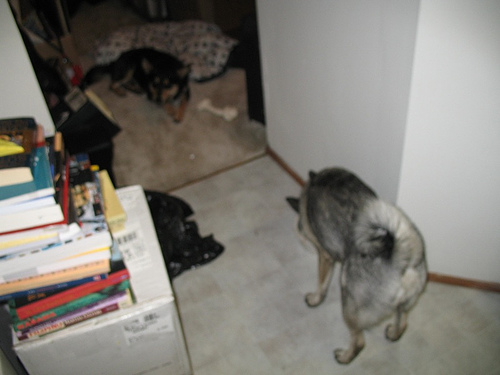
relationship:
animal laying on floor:
[75, 46, 191, 122] [164, 117, 337, 293]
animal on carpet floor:
[75, 46, 191, 122] [30, 2, 272, 195]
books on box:
[6, 105, 163, 325] [10, 185, 194, 373]